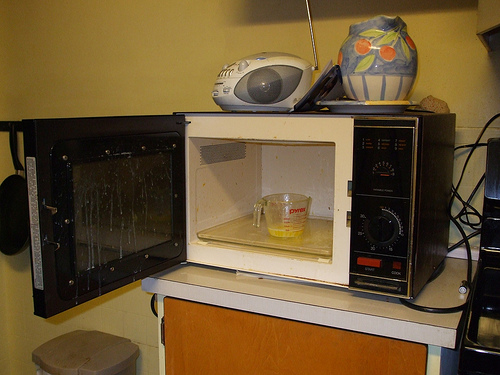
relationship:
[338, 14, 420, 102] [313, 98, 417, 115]
jar and plate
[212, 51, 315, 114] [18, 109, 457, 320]
radio on microwave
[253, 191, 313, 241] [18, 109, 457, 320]
cup in microwave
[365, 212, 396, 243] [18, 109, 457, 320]
knob on microwave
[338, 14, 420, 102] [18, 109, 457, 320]
jar on microwave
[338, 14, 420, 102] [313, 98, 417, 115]
jar on plate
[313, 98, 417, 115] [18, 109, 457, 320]
plate on microwave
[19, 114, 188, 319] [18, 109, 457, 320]
door on microwave